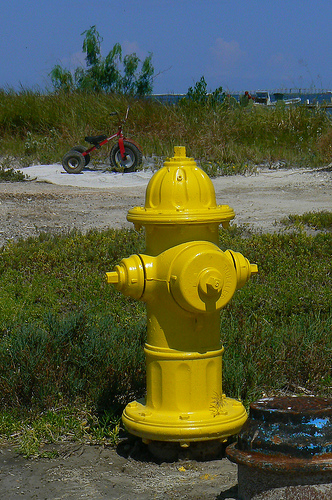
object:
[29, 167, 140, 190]
sand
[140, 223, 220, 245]
shadow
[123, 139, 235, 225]
hydrant cover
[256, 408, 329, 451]
paint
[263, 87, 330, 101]
bridge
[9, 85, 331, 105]
horizon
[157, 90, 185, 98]
water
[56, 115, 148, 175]
bicycle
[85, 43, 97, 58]
leaves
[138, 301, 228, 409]
pipe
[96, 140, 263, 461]
fire hydrant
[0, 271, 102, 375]
grass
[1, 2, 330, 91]
sky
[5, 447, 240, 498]
paved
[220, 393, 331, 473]
top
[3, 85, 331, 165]
grass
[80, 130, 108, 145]
seat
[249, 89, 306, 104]
boat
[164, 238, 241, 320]
pipe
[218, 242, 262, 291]
pipe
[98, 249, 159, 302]
pipe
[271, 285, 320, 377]
weeds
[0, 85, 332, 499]
ground